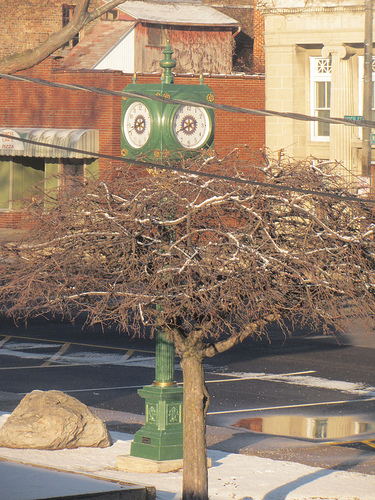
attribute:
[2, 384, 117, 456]
rock — brown, gray, large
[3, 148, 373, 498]
tree — bare, large, brown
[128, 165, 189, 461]
pole — green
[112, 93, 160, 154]
clock — green, tall, large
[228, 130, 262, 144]
bricks — red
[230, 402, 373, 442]
puddle — water puddle, large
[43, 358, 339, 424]
area — marked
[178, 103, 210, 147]
face — white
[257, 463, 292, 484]
snow — laying, white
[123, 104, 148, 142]
face — white